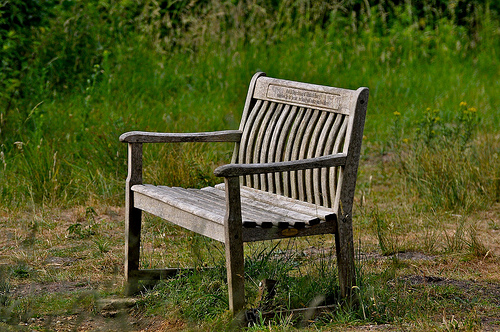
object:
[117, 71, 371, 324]
bench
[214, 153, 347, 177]
arm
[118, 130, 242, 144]
arm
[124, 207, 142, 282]
leg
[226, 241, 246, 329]
left leg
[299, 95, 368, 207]
left back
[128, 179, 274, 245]
support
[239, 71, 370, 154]
back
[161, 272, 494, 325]
weeds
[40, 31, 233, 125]
field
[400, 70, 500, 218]
grass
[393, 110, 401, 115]
flowers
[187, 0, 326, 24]
tips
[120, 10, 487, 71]
grass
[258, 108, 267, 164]
slats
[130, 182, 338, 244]
seat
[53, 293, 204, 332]
dirt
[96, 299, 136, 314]
stone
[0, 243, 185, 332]
ground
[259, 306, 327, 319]
stump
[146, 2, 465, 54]
trees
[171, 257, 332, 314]
grass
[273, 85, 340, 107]
words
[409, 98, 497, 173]
bush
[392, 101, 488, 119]
dandelions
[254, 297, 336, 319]
stick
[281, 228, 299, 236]
oval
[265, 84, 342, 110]
rectangular